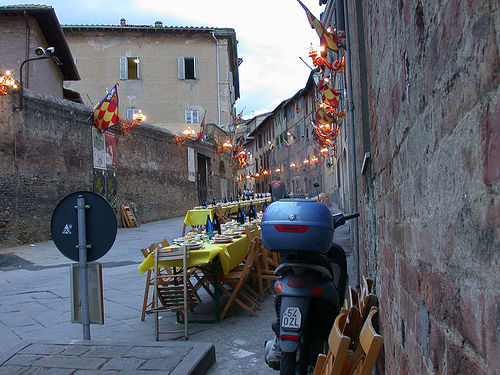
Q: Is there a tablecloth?
A: Yes, there is a tablecloth.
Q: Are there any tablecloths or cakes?
A: Yes, there is a tablecloth.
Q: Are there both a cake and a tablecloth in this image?
A: No, there is a tablecloth but no cakes.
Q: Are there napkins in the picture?
A: No, there are no napkins.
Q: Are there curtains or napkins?
A: No, there are no napkins or curtains.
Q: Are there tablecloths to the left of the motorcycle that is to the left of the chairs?
A: Yes, there is a tablecloth to the left of the motorbike.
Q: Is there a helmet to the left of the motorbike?
A: No, there is a tablecloth to the left of the motorbike.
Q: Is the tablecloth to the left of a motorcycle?
A: Yes, the tablecloth is to the left of a motorcycle.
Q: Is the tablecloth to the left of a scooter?
A: No, the tablecloth is to the left of a motorcycle.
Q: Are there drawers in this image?
A: No, there are no drawers.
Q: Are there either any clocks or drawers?
A: No, there are no drawers or clocks.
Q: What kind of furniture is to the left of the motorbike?
A: The pieces of furniture are tables.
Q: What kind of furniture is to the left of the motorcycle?
A: The pieces of furniture are tables.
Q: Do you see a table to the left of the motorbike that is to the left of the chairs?
A: Yes, there are tables to the left of the motorbike.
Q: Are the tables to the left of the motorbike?
A: Yes, the tables are to the left of the motorbike.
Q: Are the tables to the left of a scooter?
A: No, the tables are to the left of the motorbike.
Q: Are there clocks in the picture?
A: No, there are no clocks.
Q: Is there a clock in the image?
A: No, there are no clocks.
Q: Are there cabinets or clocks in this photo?
A: No, there are no clocks or cabinets.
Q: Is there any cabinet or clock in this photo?
A: No, there are no clocks or cabinets.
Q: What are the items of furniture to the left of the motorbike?
A: The pieces of furniture are chairs.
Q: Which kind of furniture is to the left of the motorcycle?
A: The pieces of furniture are chairs.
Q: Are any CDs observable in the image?
A: No, there are no cds.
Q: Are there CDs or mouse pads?
A: No, there are no CDs or mouse pads.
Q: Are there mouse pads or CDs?
A: No, there are no CDs or mouse pads.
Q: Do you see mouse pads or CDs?
A: No, there are no CDs or mouse pads.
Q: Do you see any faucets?
A: No, there are no faucets.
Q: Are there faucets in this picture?
A: No, there are no faucets.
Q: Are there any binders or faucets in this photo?
A: No, there are no faucets or binders.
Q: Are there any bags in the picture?
A: No, there are no bags.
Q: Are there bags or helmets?
A: No, there are no bags or helmets.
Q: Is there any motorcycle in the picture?
A: Yes, there is a motorcycle.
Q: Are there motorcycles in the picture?
A: Yes, there is a motorcycle.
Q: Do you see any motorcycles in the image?
A: Yes, there is a motorcycle.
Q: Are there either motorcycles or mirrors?
A: Yes, there is a motorcycle.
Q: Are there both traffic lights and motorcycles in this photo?
A: No, there is a motorcycle but no traffic lights.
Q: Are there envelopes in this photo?
A: No, there are no envelopes.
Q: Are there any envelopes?
A: No, there are no envelopes.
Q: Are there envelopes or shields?
A: No, there are no envelopes or shields.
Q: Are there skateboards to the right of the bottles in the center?
A: No, there is a motorcycle to the right of the bottles.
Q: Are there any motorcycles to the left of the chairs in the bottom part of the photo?
A: Yes, there is a motorcycle to the left of the chairs.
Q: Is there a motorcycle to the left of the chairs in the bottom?
A: Yes, there is a motorcycle to the left of the chairs.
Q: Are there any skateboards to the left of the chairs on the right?
A: No, there is a motorcycle to the left of the chairs.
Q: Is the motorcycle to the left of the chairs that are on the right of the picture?
A: Yes, the motorcycle is to the left of the chairs.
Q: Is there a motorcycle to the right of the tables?
A: Yes, there is a motorcycle to the right of the tables.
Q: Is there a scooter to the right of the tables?
A: No, there is a motorcycle to the right of the tables.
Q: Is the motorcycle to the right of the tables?
A: Yes, the motorcycle is to the right of the tables.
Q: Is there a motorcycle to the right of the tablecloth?
A: Yes, there is a motorcycle to the right of the tablecloth.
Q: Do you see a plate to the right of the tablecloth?
A: No, there is a motorcycle to the right of the tablecloth.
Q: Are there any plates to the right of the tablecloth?
A: No, there is a motorcycle to the right of the tablecloth.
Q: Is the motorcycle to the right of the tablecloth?
A: Yes, the motorcycle is to the right of the tablecloth.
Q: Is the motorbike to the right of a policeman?
A: No, the motorbike is to the right of the tablecloth.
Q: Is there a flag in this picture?
A: Yes, there is a flag.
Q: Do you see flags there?
A: Yes, there is a flag.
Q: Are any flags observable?
A: Yes, there is a flag.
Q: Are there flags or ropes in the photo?
A: Yes, there is a flag.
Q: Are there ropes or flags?
A: Yes, there is a flag.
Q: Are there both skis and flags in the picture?
A: No, there is a flag but no skis.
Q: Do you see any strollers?
A: No, there are no strollers.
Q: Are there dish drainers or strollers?
A: No, there are no strollers or dish drainers.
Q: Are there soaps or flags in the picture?
A: Yes, there is a flag.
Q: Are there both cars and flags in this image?
A: No, there is a flag but no cars.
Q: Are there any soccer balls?
A: No, there are no soccer balls.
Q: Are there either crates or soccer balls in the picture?
A: No, there are no soccer balls or crates.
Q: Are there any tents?
A: No, there are no tents.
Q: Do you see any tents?
A: No, there are no tents.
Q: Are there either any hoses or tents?
A: No, there are no tents or hoses.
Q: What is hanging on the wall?
A: The poster is hanging on the wall.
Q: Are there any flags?
A: Yes, there is a flag.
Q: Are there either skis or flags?
A: Yes, there is a flag.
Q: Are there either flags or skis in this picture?
A: Yes, there is a flag.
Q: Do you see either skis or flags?
A: Yes, there is a flag.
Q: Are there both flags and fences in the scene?
A: No, there is a flag but no fences.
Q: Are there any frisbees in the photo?
A: No, there are no frisbees.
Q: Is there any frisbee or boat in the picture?
A: No, there are no frisbees or boats.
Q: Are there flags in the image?
A: Yes, there is a flag.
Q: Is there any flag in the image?
A: Yes, there is a flag.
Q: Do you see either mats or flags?
A: Yes, there is a flag.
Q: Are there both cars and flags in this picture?
A: No, there is a flag but no cars.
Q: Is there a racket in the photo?
A: No, there are no rackets.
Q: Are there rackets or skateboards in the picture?
A: No, there are no rackets or skateboards.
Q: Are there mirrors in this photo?
A: No, there are no mirrors.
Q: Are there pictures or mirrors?
A: No, there are no mirrors or pictures.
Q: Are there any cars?
A: No, there are no cars.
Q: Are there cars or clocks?
A: No, there are no cars or clocks.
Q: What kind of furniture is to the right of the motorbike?
A: The pieces of furniture are chairs.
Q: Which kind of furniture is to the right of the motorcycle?
A: The pieces of furniture are chairs.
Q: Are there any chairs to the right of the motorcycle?
A: Yes, there are chairs to the right of the motorcycle.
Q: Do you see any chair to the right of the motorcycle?
A: Yes, there are chairs to the right of the motorcycle.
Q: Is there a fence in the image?
A: No, there are no fences.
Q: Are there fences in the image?
A: No, there are no fences.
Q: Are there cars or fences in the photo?
A: No, there are no fences or cars.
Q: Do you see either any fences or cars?
A: No, there are no fences or cars.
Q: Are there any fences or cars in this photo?
A: No, there are no fences or cars.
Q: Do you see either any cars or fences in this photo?
A: No, there are no fences or cars.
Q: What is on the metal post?
A: The sign is on the post.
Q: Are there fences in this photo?
A: No, there are no fences.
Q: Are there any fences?
A: No, there are no fences.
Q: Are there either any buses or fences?
A: No, there are no fences or buses.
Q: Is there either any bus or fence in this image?
A: No, there are no fences or buses.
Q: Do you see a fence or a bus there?
A: No, there are no fences or buses.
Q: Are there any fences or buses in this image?
A: No, there are no fences or buses.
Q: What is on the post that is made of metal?
A: The sign is on the post.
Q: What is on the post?
A: The sign is on the post.